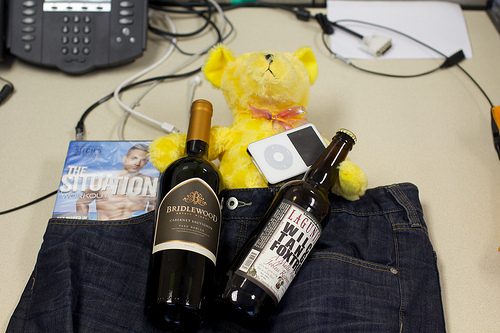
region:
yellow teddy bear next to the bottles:
[147, 44, 364, 199]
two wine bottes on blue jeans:
[142, 99, 357, 331]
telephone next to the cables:
[0, 1, 146, 76]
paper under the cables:
[325, 1, 474, 63]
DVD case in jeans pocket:
[50, 139, 160, 229]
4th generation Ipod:
[245, 121, 328, 182]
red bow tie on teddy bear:
[245, 104, 312, 129]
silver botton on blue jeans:
[222, 196, 243, 210]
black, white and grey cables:
[75, 1, 237, 141]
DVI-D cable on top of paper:
[350, 29, 393, 58]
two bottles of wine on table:
[112, 103, 377, 305]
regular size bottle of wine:
[126, 89, 233, 316]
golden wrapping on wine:
[171, 99, 221, 151]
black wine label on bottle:
[148, 180, 220, 265]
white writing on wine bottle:
[158, 194, 218, 239]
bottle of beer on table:
[217, 114, 354, 308]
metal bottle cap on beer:
[338, 119, 359, 142]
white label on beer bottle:
[234, 194, 331, 290]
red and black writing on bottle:
[220, 203, 331, 294]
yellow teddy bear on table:
[158, 31, 345, 187]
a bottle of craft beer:
[223, 128, 356, 328]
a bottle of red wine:
[147, 93, 222, 325]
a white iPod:
[249, 123, 328, 184]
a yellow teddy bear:
[150, 43, 365, 198]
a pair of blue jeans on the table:
[6, 182, 445, 329]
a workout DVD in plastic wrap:
[50, 140, 160, 221]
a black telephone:
[8, 0, 146, 77]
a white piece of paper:
[326, 5, 466, 58]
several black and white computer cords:
[74, 6, 490, 139]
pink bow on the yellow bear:
[253, 104, 303, 127]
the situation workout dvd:
[60, 130, 162, 245]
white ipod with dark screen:
[246, 117, 333, 181]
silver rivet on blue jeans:
[218, 188, 248, 214]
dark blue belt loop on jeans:
[380, 176, 439, 236]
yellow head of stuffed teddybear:
[218, 40, 340, 100]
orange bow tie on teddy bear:
[237, 90, 316, 125]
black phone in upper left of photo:
[23, 19, 162, 71]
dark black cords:
[326, 52, 486, 86]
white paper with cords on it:
[351, 3, 479, 61]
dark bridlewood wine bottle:
[139, 94, 238, 317]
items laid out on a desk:
[1, 43, 493, 331]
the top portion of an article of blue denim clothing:
[5, 182, 447, 332]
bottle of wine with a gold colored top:
[145, 98, 221, 326]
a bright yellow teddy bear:
[148, 44, 368, 200]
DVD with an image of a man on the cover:
[54, 137, 156, 222]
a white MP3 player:
[247, 122, 324, 182]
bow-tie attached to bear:
[243, 100, 307, 136]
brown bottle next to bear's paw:
[218, 128, 366, 325]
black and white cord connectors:
[306, 16, 468, 84]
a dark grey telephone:
[2, 0, 149, 75]